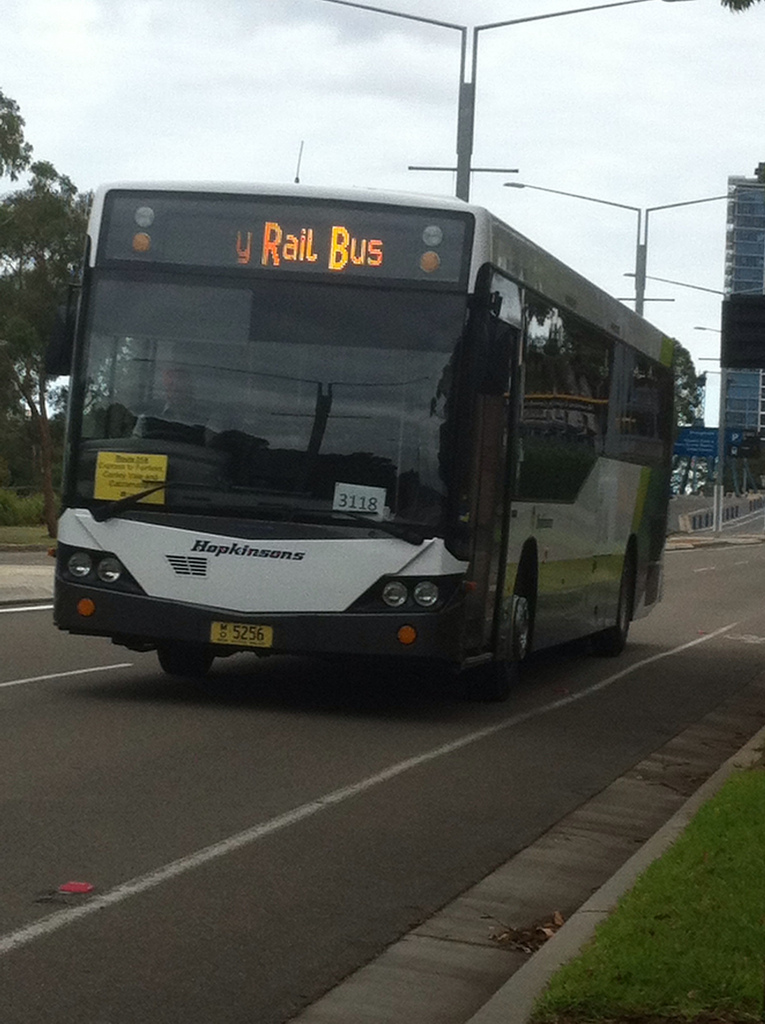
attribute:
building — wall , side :
[682, 173, 741, 472]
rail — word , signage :
[682, 482, 736, 540]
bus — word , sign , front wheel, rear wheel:
[39, 178, 705, 717]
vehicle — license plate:
[39, 173, 706, 708]